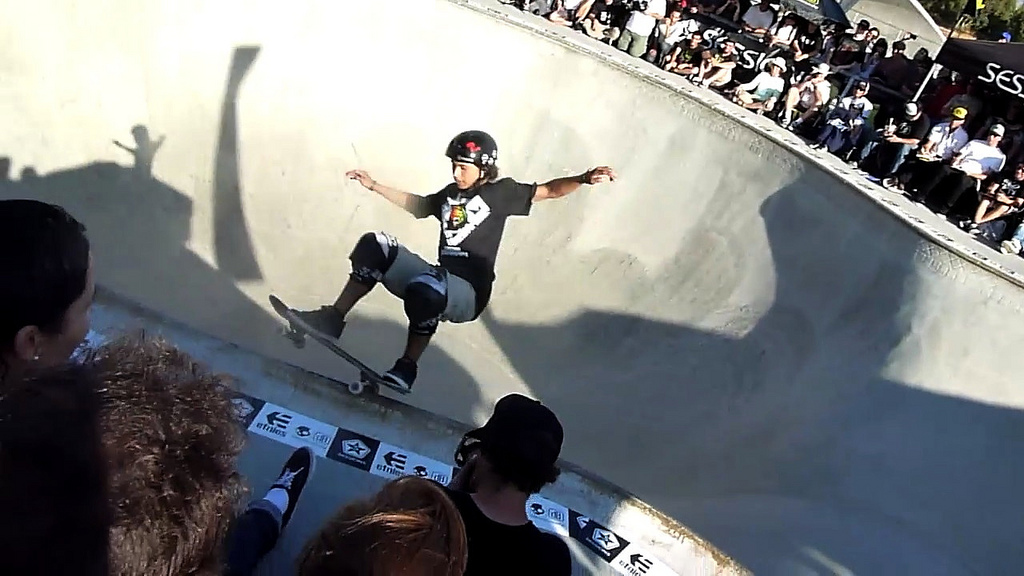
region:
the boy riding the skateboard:
[266, 117, 620, 393]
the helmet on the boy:
[441, 132, 498, 190]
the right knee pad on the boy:
[345, 220, 400, 284]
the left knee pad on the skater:
[399, 267, 453, 329]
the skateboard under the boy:
[268, 293, 395, 401]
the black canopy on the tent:
[941, 34, 1022, 98]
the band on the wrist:
[365, 173, 381, 196]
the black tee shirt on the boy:
[426, 174, 540, 318]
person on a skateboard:
[302, 120, 629, 386]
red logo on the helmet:
[460, 136, 486, 155]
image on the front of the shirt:
[435, 187, 499, 257]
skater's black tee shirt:
[419, 165, 543, 280]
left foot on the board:
[381, 357, 424, 392]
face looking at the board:
[443, 158, 478, 191]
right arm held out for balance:
[338, 161, 434, 215]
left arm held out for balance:
[508, 160, 614, 208]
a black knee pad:
[399, 270, 445, 322]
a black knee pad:
[348, 234, 397, 274]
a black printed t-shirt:
[428, 177, 536, 314]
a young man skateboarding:
[269, 128, 618, 397]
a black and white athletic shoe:
[384, 354, 416, 389]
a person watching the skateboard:
[904, 84, 943, 186]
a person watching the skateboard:
[878, 41, 910, 162]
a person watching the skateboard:
[812, 57, 860, 179]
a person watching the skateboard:
[746, 59, 803, 129]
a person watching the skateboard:
[887, 10, 910, 88]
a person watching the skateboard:
[351, 452, 438, 566]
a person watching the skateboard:
[101, 400, 190, 550]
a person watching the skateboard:
[439, 430, 545, 535]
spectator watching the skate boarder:
[942, 118, 999, 217]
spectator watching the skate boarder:
[893, 96, 970, 191]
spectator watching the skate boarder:
[864, 93, 926, 180]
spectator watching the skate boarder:
[814, 77, 873, 147]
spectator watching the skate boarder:
[772, 43, 837, 126]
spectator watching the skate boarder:
[694, 17, 739, 87]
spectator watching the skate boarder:
[447, 365, 591, 568]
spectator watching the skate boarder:
[295, 450, 485, 568]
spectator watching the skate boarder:
[1, 310, 321, 573]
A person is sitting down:
[814, 80, 875, 163]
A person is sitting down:
[689, 36, 737, 95]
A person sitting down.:
[645, 8, 685, 66]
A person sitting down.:
[2, 334, 317, 572]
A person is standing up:
[828, 17, 868, 90]